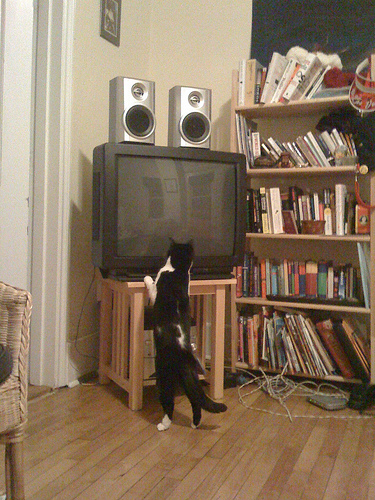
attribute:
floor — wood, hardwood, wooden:
[0, 377, 374, 498]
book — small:
[242, 260, 360, 300]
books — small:
[245, 254, 361, 300]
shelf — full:
[240, 155, 363, 183]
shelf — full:
[243, 226, 370, 246]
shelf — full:
[233, 289, 370, 319]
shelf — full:
[232, 355, 364, 394]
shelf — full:
[234, 301, 373, 386]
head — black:
[167, 234, 195, 264]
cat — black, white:
[141, 223, 201, 383]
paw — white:
[155, 421, 165, 430]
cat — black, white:
[142, 234, 227, 431]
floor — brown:
[2, 352, 374, 498]